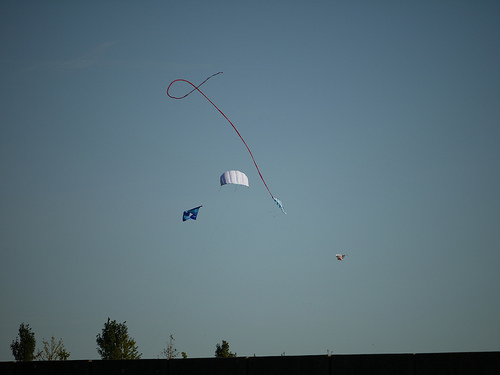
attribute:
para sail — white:
[215, 165, 252, 200]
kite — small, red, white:
[318, 246, 352, 271]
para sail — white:
[204, 140, 295, 200]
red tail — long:
[165, 65, 274, 198]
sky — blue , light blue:
[7, 2, 496, 357]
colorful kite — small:
[331, 250, 346, 264]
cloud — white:
[9, 32, 129, 80]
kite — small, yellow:
[335, 254, 347, 262]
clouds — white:
[42, 41, 162, 98]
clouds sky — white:
[290, 37, 491, 226]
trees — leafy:
[13, 308, 273, 363]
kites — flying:
[215, 168, 265, 198]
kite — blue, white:
[217, 170, 249, 189]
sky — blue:
[113, 25, 183, 82]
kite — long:
[271, 197, 286, 217]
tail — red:
[164, 69, 271, 199]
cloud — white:
[2, 30, 177, 72]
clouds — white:
[4, 3, 498, 365]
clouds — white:
[6, 16, 143, 96]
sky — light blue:
[9, 11, 498, 277]